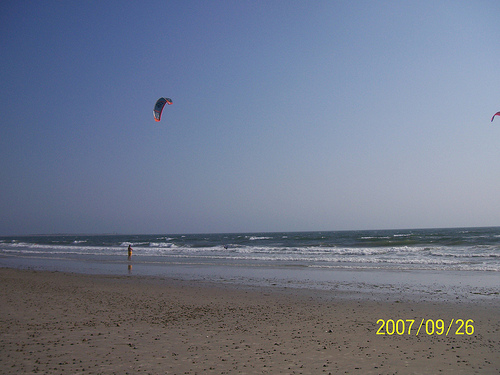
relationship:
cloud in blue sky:
[0, 0, 499, 205] [41, 27, 128, 118]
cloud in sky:
[0, 0, 499, 205] [276, 38, 398, 104]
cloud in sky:
[0, 0, 499, 205] [13, 14, 498, 250]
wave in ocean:
[117, 239, 180, 253] [1, 225, 498, 269]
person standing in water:
[126, 241, 139, 271] [0, 228, 498, 299]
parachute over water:
[485, 98, 499, 125] [242, 220, 438, 269]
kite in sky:
[152, 95, 171, 125] [0, 0, 499, 228]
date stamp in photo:
[375, 317, 475, 337] [1, 0, 498, 374]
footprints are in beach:
[7, 299, 432, 370] [0, 224, 499, 373]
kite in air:
[152, 96, 173, 122] [1, 0, 499, 191]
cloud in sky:
[0, 0, 499, 205] [0, 0, 499, 228]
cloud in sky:
[0, 0, 499, 205] [199, 47, 466, 199]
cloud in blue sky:
[0, 0, 499, 205] [6, 4, 499, 230]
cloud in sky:
[0, 0, 499, 205] [286, 74, 431, 181]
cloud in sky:
[0, 0, 499, 205] [338, 13, 470, 98]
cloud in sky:
[0, 0, 499, 205] [30, 45, 455, 211]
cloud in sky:
[35, 137, 139, 199] [0, 0, 499, 228]